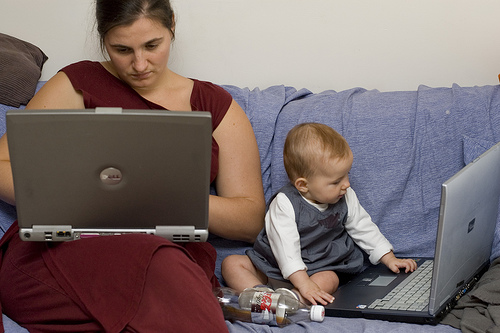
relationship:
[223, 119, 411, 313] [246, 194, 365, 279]
baby in dress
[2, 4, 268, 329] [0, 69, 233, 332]
lady in dress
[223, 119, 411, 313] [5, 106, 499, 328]
baby playing on computer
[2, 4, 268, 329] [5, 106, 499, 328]
lady working computer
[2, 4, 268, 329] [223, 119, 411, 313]
mother and child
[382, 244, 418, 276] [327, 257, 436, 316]
hand near keyboard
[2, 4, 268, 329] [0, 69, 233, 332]
mother wearing outfit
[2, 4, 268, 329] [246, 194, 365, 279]
mother wearing dress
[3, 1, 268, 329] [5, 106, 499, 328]
lady looking at computer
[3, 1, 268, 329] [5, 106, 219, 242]
lady looking at computer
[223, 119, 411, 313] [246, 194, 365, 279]
baby wearing jumper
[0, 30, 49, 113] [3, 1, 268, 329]
pillow near lady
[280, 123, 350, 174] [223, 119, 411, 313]
hair on baby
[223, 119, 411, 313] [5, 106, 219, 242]
baby looking at computer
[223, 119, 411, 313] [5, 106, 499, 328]
baby looking at computer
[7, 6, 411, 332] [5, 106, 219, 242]
family using computer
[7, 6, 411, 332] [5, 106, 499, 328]
family using computer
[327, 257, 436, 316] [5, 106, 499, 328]
keyboard on computer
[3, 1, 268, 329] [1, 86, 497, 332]
lady on couch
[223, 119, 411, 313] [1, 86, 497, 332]
child on couch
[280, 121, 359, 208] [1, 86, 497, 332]
head on couch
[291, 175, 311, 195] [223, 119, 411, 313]
ear of child